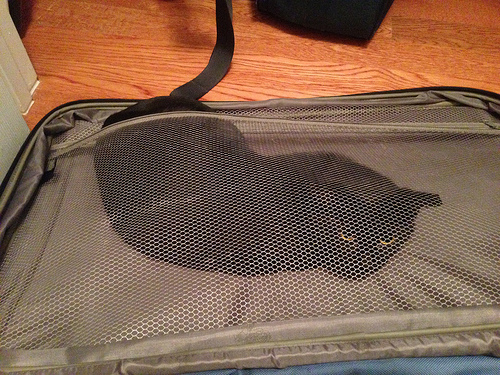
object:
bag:
[1, 83, 499, 373]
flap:
[0, 104, 500, 360]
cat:
[91, 0, 439, 284]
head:
[305, 182, 444, 281]